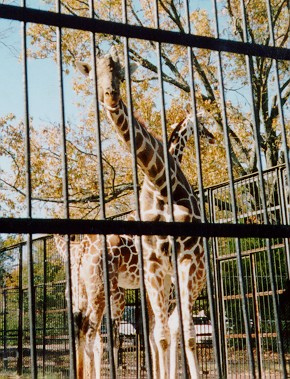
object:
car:
[192, 315, 212, 344]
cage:
[0, 2, 287, 377]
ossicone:
[110, 45, 120, 63]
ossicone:
[89, 52, 100, 67]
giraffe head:
[75, 46, 139, 108]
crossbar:
[0, 3, 290, 62]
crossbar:
[2, 216, 290, 240]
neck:
[168, 123, 191, 166]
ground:
[223, 95, 237, 110]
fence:
[0, 164, 288, 378]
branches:
[55, 0, 247, 159]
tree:
[71, 1, 288, 161]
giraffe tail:
[71, 241, 85, 343]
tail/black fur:
[66, 241, 90, 340]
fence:
[0, 0, 290, 379]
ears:
[73, 60, 93, 78]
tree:
[30, 1, 288, 162]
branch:
[245, 0, 290, 175]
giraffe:
[73, 101, 212, 379]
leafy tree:
[0, 1, 283, 238]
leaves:
[202, 149, 223, 186]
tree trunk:
[205, 179, 281, 231]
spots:
[118, 242, 131, 262]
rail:
[221, 289, 285, 301]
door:
[209, 169, 290, 379]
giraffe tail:
[42, 205, 101, 378]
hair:
[73, 311, 83, 346]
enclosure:
[0, 3, 288, 379]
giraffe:
[74, 45, 211, 379]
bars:
[18, 0, 38, 379]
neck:
[105, 99, 188, 200]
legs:
[177, 269, 209, 379]